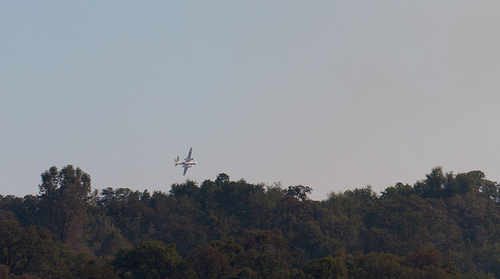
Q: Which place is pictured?
A: It is a forest.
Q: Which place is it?
A: It is a forest.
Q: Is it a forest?
A: Yes, it is a forest.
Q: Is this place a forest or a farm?
A: It is a forest.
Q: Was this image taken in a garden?
A: No, the picture was taken in a forest.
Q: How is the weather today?
A: It is clear.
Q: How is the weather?
A: It is clear.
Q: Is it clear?
A: Yes, it is clear.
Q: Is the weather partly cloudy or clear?
A: It is clear.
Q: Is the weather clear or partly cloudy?
A: It is clear.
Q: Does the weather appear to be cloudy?
A: No, it is clear.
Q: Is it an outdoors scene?
A: Yes, it is outdoors.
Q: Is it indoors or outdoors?
A: It is outdoors.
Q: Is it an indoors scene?
A: No, it is outdoors.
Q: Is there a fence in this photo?
A: No, there are no fences.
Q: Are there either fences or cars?
A: No, there are no fences or cars.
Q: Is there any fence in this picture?
A: No, there are no fences.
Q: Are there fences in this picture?
A: No, there are no fences.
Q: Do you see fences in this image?
A: No, there are no fences.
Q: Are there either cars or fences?
A: No, there are no fences or cars.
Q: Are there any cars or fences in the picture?
A: No, there are no fences or cars.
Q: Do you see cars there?
A: No, there are no cars.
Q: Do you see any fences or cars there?
A: No, there are no cars or fences.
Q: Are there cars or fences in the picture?
A: No, there are no cars or fences.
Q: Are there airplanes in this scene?
A: Yes, there is an airplane.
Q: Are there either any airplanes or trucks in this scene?
A: Yes, there is an airplane.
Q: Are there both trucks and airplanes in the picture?
A: No, there is an airplane but no trucks.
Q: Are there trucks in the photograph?
A: No, there are no trucks.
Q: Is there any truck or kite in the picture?
A: No, there are no trucks or kites.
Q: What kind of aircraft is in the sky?
A: The aircraft is an airplane.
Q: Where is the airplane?
A: The airplane is in the sky.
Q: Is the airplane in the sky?
A: Yes, the airplane is in the sky.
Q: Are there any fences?
A: No, there are no fences.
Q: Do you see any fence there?
A: No, there are no fences.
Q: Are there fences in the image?
A: No, there are no fences.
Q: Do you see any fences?
A: No, there are no fences.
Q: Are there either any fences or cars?
A: No, there are no fences or cars.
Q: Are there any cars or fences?
A: No, there are no fences or cars.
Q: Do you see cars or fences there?
A: No, there are no fences or cars.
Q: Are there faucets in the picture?
A: No, there are no faucets.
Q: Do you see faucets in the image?
A: No, there are no faucets.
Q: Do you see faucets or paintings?
A: No, there are no faucets or paintings.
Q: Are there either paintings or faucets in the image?
A: No, there are no faucets or paintings.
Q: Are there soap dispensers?
A: No, there are no soap dispensers.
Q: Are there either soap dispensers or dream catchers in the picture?
A: No, there are no soap dispensers or dream catchers.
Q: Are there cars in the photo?
A: No, there are no cars.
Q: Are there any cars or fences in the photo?
A: No, there are no cars or fences.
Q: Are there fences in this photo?
A: No, there are no fences.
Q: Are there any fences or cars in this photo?
A: No, there are no fences or cars.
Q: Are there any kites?
A: No, there are no kites.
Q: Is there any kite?
A: No, there are no kites.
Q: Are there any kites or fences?
A: No, there are no kites or fences.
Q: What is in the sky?
A: The clouds are in the sky.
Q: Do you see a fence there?
A: No, there are no fences.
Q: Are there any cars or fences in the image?
A: No, there are no fences or cars.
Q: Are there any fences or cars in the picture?
A: No, there are no fences or cars.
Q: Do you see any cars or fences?
A: No, there are no fences or cars.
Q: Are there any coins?
A: No, there are no coins.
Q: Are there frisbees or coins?
A: No, there are no coins or frisbees.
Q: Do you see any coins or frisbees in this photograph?
A: No, there are no coins or frisbees.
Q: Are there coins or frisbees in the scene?
A: No, there are no coins or frisbees.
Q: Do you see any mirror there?
A: No, there are no mirrors.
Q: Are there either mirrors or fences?
A: No, there are no mirrors or fences.